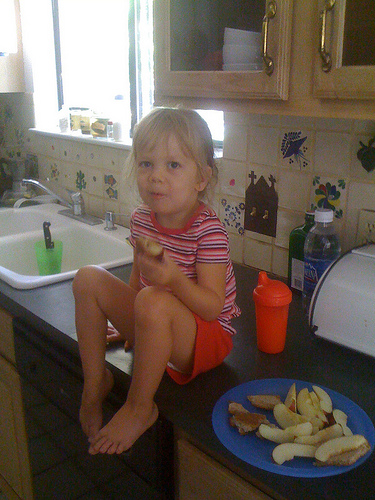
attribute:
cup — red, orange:
[252, 271, 294, 357]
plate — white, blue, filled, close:
[218, 371, 369, 478]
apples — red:
[272, 399, 334, 439]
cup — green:
[32, 242, 67, 274]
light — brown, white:
[241, 175, 279, 240]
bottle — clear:
[306, 204, 338, 277]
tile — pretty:
[42, 144, 130, 204]